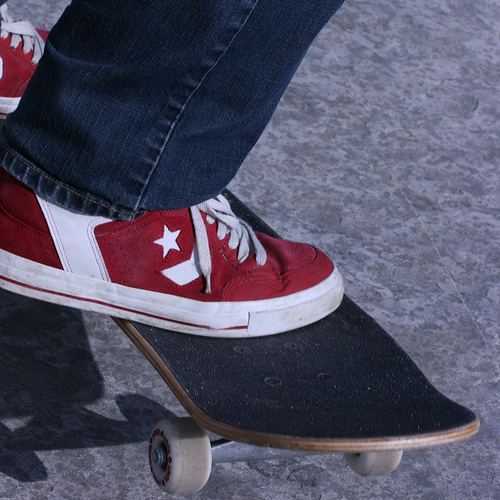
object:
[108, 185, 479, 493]
skatebord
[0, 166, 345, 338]
tennis shoe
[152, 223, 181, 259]
star design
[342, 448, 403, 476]
wheel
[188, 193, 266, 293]
laces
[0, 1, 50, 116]
tennis shoe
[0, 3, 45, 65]
laces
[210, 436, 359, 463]
axel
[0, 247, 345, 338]
rubber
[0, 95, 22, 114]
rubber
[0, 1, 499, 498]
picture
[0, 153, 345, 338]
shoes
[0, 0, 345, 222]
jeans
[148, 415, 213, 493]
wheels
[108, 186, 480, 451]
grip tape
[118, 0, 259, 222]
seam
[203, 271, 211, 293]
aglet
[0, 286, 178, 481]
shadow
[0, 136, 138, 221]
stitching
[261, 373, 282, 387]
bolts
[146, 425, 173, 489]
design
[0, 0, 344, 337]
person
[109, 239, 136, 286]
air holes